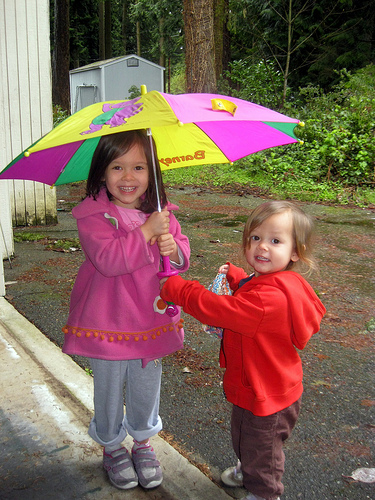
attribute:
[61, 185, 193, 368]
shirt — pink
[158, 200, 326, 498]
child — young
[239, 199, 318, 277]
hair — short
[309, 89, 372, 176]
green trees — leafy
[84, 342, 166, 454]
pants — grey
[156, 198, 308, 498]
child — young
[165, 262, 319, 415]
shirt — red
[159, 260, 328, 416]
jacket — red, hooded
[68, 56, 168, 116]
shed — small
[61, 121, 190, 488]
girl — young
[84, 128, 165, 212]
hair — brown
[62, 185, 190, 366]
long sleeve — long-sleeved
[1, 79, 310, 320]
umbrella — yellow, purple, green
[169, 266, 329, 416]
sweater — long-sleeved, red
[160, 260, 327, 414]
sweatshirt. — red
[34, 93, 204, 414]
girl — young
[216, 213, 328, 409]
child — young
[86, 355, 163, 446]
pants — rolled up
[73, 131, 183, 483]
girl — young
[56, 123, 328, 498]
kids — smiling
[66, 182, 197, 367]
coat — pink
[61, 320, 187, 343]
fringe — orange ball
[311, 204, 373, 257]
moss — green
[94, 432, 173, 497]
sneaker — feminine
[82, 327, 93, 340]
pom pom — orange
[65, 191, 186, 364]
coat — small, trimmed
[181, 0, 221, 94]
trunk — large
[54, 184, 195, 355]
coat — pink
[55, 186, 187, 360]
sweater — pink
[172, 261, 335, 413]
sweat shirt — red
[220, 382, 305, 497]
pants — brown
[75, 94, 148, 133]
character — cartoon